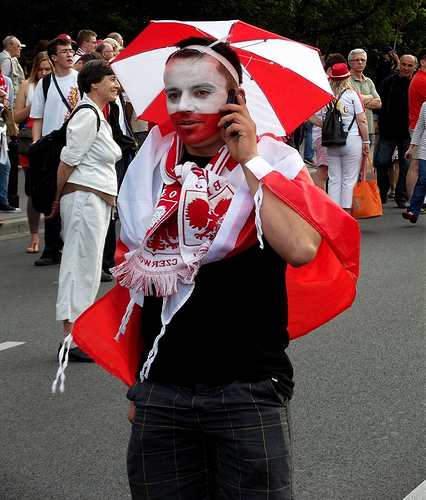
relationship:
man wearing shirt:
[49, 34, 362, 500] [118, 182, 329, 349]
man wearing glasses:
[49, 34, 362, 500] [52, 48, 75, 55]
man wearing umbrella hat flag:
[125, 35, 324, 498] [57, 124, 361, 382]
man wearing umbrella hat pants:
[49, 34, 362, 500] [122, 371, 296, 498]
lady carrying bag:
[319, 63, 371, 216] [349, 143, 387, 220]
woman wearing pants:
[53, 55, 121, 311] [41, 187, 132, 316]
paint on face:
[160, 58, 230, 116] [150, 41, 232, 117]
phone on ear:
[225, 91, 241, 130] [233, 83, 247, 103]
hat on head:
[325, 63, 354, 83] [328, 68, 350, 92]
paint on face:
[160, 58, 230, 116] [160, 37, 245, 148]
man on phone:
[49, 34, 362, 500] [140, 30, 395, 146]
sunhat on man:
[104, 17, 338, 140] [125, 35, 324, 498]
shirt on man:
[127, 153, 293, 396] [49, 19, 358, 498]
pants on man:
[126, 379, 292, 497] [49, 19, 358, 498]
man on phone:
[49, 34, 362, 500] [224, 85, 242, 133]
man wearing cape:
[49, 34, 362, 500] [69, 123, 359, 386]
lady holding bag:
[319, 63, 371, 216] [350, 145, 383, 217]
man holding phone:
[125, 35, 324, 498] [222, 86, 239, 130]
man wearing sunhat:
[49, 34, 362, 500] [104, 17, 338, 140]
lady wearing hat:
[319, 63, 371, 216] [325, 63, 354, 83]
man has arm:
[342, 45, 388, 166] [347, 83, 375, 108]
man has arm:
[342, 45, 388, 166] [364, 74, 387, 111]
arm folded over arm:
[347, 83, 375, 108] [364, 74, 387, 111]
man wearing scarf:
[125, 35, 324, 498] [81, 119, 307, 300]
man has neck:
[125, 35, 324, 498] [186, 141, 226, 158]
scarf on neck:
[81, 119, 307, 300] [186, 141, 226, 158]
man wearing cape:
[125, 35, 324, 498] [69, 123, 359, 386]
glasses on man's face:
[58, 45, 78, 57] [56, 42, 76, 71]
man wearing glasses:
[28, 36, 80, 253] [58, 45, 78, 57]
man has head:
[125, 35, 324, 498] [157, 39, 245, 144]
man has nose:
[125, 35, 324, 498] [174, 92, 192, 116]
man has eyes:
[49, 34, 362, 500] [159, 77, 225, 101]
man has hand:
[125, 35, 324, 498] [215, 87, 259, 159]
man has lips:
[49, 34, 362, 500] [176, 121, 201, 130]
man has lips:
[49, 34, 362, 500] [176, 115, 204, 123]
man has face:
[125, 35, 324, 498] [162, 55, 226, 146]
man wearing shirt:
[125, 35, 324, 498] [127, 153, 293, 396]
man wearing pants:
[125, 35, 324, 498] [126, 379, 296, 500]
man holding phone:
[125, 35, 324, 498] [224, 86, 244, 127]